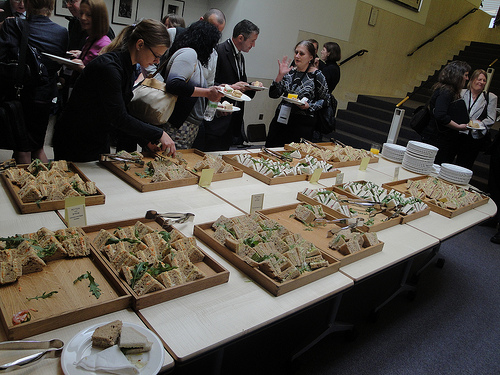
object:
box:
[193, 212, 340, 297]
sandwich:
[261, 258, 282, 279]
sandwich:
[212, 214, 235, 230]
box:
[0, 158, 107, 215]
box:
[1, 227, 131, 341]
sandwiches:
[133, 272, 166, 297]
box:
[222, 152, 307, 186]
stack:
[382, 142, 406, 164]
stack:
[402, 139, 438, 175]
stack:
[438, 163, 473, 187]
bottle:
[203, 86, 223, 121]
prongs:
[145, 209, 195, 228]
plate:
[218, 85, 252, 102]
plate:
[217, 103, 241, 112]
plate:
[280, 96, 305, 106]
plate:
[466, 125, 485, 129]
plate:
[245, 84, 269, 91]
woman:
[268, 40, 333, 145]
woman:
[415, 60, 472, 162]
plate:
[40, 52, 83, 67]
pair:
[144, 44, 170, 61]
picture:
[160, 1, 185, 22]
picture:
[111, 1, 140, 27]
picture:
[54, 1, 79, 19]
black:
[403, 10, 477, 58]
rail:
[338, 49, 366, 66]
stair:
[459, 49, 498, 59]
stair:
[333, 117, 407, 146]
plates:
[440, 163, 472, 173]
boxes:
[380, 174, 491, 218]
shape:
[21, 252, 46, 273]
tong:
[1, 339, 65, 373]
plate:
[61, 319, 165, 374]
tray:
[82, 214, 229, 310]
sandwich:
[120, 326, 149, 347]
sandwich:
[92, 319, 122, 348]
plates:
[405, 150, 434, 160]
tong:
[99, 154, 144, 168]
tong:
[260, 146, 293, 163]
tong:
[299, 137, 327, 151]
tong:
[331, 138, 346, 148]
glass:
[370, 143, 381, 157]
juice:
[370, 147, 379, 154]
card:
[65, 197, 87, 227]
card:
[250, 193, 265, 214]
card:
[336, 172, 345, 186]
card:
[198, 169, 215, 187]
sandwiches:
[217, 164, 235, 174]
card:
[309, 169, 323, 185]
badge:
[276, 103, 291, 125]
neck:
[296, 65, 311, 71]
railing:
[405, 8, 478, 58]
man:
[206, 19, 261, 145]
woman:
[51, 19, 175, 163]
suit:
[213, 41, 247, 147]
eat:
[232, 140, 372, 178]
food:
[406, 176, 485, 211]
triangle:
[19, 185, 42, 201]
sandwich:
[150, 169, 170, 183]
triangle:
[41, 244, 67, 262]